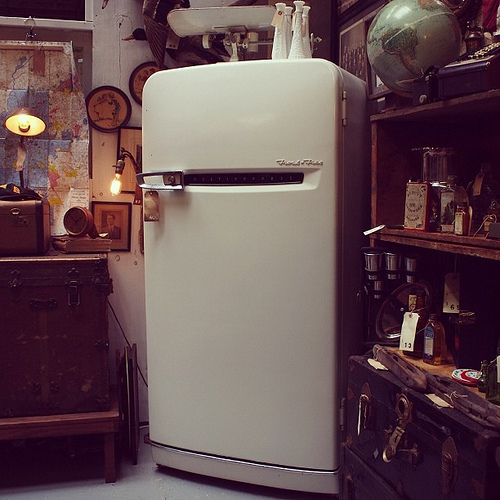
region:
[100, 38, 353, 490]
the refrigerator is big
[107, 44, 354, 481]
the refrigerator is white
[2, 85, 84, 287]
the lamp is on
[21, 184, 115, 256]
a clock is on the book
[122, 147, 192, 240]
the handle has a tag on it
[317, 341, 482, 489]
trunk to the right of the fridge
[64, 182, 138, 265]
picture on the wall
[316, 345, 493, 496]
the trunk is black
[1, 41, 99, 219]
a map behind the lamp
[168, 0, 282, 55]
a scale on top of the fridge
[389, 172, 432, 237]
Small decorative antique on shelf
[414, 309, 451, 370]
Small decorative antique on shelf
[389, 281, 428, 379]
Small decorative antique on shelf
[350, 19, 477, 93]
Small decorative antique on shelf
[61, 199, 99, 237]
Small decorative antique on shelf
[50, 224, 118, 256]
Small decorative antique on shelf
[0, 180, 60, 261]
Small decorative antique on shelf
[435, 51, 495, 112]
Small decorative antique on shelf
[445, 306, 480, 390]
Small decorative antique on shelf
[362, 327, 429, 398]
Small decorative antique on shelf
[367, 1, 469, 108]
Globe on shelf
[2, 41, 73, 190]
Map hanging on wall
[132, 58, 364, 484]
Old refrigerator diagonal in corner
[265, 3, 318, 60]
Four milk white vases on top of refrigerator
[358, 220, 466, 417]
Items with tags on shelf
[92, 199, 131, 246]
Aged photo in black frame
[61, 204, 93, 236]
Old red alarm clock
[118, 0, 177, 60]
Ducks hanging on a wall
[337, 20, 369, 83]
Aged group photo on wall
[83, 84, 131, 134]
Aged picture in round frame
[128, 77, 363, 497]
white refrigerator with latch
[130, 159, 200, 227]
white fridge with latch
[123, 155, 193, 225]
lock pad on fridge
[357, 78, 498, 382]
shelf filled with items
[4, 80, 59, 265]
lamp on brown chest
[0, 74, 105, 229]
map hanging on wall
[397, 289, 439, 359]
bottle on brown shelf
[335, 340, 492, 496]
black chest under shelf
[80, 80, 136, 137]
circular wall decor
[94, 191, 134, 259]
wooden picture frame on wall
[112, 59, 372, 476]
an old timey refridgerator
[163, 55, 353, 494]
the fridge is white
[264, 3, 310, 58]
four milk glass vases sit on top of the fridge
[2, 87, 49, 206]
a desk light is turned on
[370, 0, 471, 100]
a globe is on the shelf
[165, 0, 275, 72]
an old scale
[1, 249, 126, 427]
an old trunk sits to the side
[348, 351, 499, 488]
another old trunk is for sale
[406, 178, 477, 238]
some old bottles are for sale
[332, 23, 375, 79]
an old photograph is on the wall